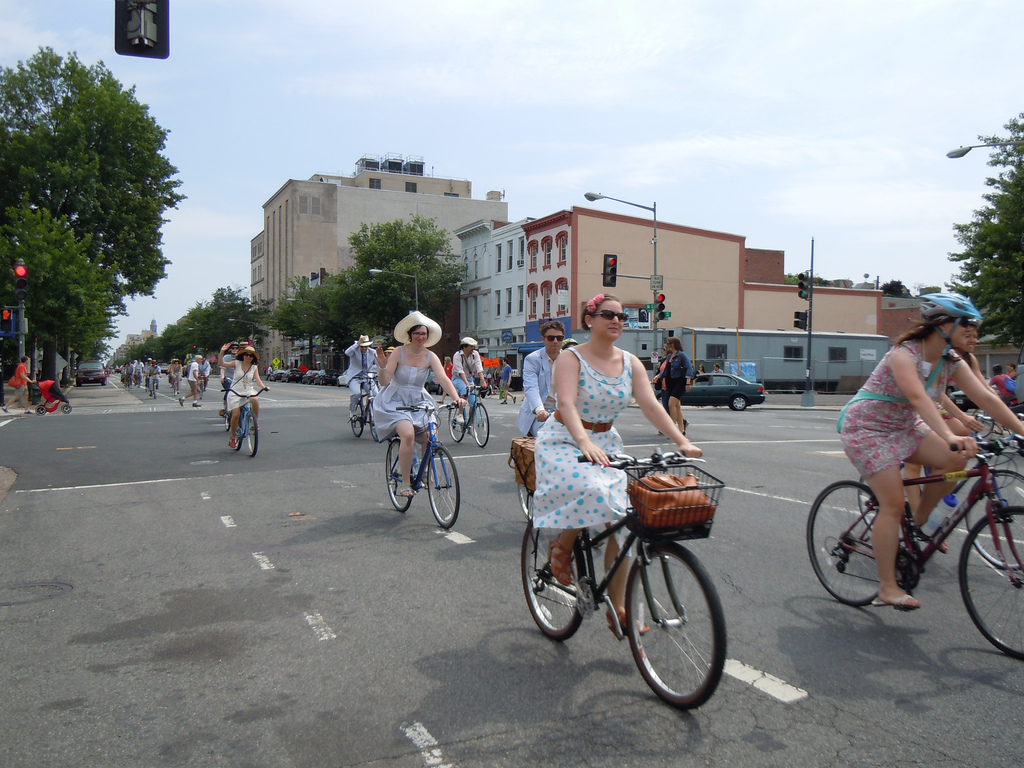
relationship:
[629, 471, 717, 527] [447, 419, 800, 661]
purse on bike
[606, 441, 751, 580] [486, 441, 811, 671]
purse on bike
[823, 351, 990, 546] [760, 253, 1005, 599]
dress on woman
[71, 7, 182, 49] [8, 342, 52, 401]
light above woman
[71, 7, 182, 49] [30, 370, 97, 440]
light above stroller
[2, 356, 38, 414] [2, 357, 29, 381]
woman with shirt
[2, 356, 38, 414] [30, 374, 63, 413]
woman with stroller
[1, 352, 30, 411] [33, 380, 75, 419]
woman pushing stroller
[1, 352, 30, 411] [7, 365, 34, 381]
woman in shirt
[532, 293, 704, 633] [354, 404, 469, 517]
woman wearing dress riding bike